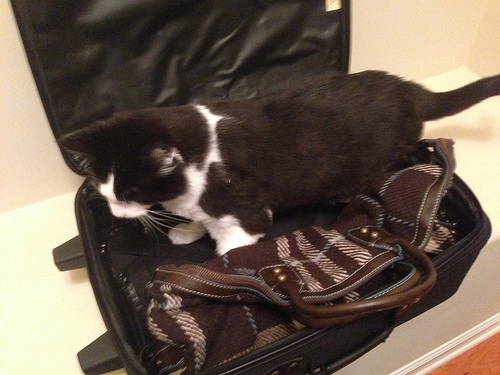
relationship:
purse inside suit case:
[146, 190, 498, 347] [13, 0, 495, 375]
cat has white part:
[35, 27, 498, 260] [102, 165, 254, 258]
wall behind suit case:
[1, 2, 500, 204] [13, 0, 495, 375]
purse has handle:
[146, 190, 498, 347] [272, 244, 446, 326]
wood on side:
[381, 292, 500, 369] [351, 12, 499, 372]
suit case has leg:
[13, 0, 495, 375] [45, 226, 113, 274]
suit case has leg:
[13, 0, 495, 375] [76, 322, 133, 375]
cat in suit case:
[35, 27, 498, 260] [13, 0, 495, 375]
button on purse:
[271, 263, 292, 288] [146, 190, 498, 347]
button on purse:
[358, 224, 382, 239] [146, 190, 498, 347]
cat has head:
[35, 27, 498, 260] [60, 100, 199, 225]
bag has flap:
[146, 190, 498, 347] [307, 233, 403, 289]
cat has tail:
[35, 27, 498, 260] [396, 66, 498, 115]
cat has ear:
[35, 27, 498, 260] [138, 135, 187, 180]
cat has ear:
[35, 27, 498, 260] [52, 132, 109, 163]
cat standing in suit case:
[35, 27, 498, 260] [13, 0, 495, 375]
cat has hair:
[35, 27, 498, 260] [88, 98, 432, 234]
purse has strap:
[146, 190, 498, 347] [272, 244, 446, 326]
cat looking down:
[35, 27, 498, 260] [46, 213, 166, 336]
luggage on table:
[13, 0, 495, 375] [5, 172, 495, 343]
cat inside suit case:
[35, 27, 498, 260] [13, 0, 495, 375]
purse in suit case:
[146, 190, 498, 347] [13, 0, 495, 375]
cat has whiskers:
[35, 27, 498, 260] [134, 202, 191, 239]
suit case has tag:
[13, 0, 495, 375] [321, 1, 345, 21]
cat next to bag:
[35, 27, 498, 260] [146, 190, 498, 347]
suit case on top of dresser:
[13, 0, 495, 375] [5, 172, 495, 343]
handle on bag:
[272, 244, 446, 326] [146, 190, 498, 347]